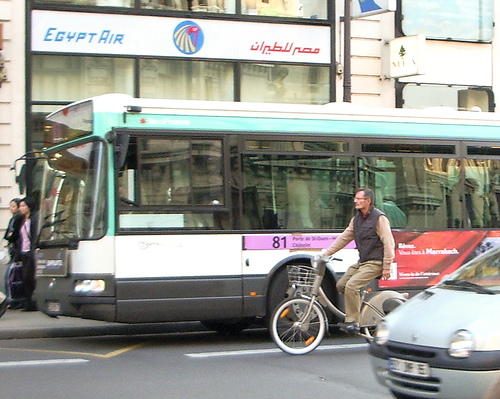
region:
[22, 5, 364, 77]
sign for Egypt Air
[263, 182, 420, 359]
man riding bike next to bus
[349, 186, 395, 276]
man wearing brown vest jacket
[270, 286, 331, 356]
two orange reflectors on bike tire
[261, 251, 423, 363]
Brown bike with basket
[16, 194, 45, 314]
woman in pink shirt on sidewalk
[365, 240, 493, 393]
small white car in street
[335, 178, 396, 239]
man wearing glasses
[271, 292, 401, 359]
white sidewall tires on bike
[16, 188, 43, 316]
woman with black hair and pants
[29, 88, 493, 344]
bus on city street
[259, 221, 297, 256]
number on side of bus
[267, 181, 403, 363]
man sitting on scooter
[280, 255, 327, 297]
basket on front of scooter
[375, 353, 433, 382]
license on front of car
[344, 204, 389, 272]
brown vest on man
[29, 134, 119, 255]
windshield on front of bus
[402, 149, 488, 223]
reflection on bus window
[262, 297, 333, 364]
scooter wheel with white wall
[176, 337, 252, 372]
white line in road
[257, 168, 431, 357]
an old man riding a bicycle down the road next to a large bus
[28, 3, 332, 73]
a sign on the building for Egypt Air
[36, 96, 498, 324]
a large city bus on the side of the road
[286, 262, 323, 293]
a silver basket on the front of the bicycle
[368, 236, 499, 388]
the front of a white car on the road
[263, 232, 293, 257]
number 81 on a purple sign on the side of the bus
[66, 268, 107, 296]
the front left headlight on the bus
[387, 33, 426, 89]
a white sign with a black logo on it on the building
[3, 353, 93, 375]
a white line painted in the street for cars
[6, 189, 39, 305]
two Asian women walking on the sidewalk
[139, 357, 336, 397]
this is the road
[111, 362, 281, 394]
the road is clear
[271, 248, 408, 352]
this is a bicycle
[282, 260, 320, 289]
this is a basket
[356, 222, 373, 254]
the jacket is brown in color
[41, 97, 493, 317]
this is a bus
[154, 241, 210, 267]
the bus is white in color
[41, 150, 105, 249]
this is a windscreen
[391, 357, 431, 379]
this is a number plate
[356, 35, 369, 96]
the wall is white in color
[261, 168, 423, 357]
man riding a bike down the street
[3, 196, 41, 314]
two people walking along the sidewalk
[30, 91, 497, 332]
large bus driving down the street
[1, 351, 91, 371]
white line painted on the ground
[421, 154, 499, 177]
reflection on the windpw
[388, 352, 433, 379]
long white license plate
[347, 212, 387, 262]
dark brown vest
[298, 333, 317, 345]
orange reflector in the spokes of the wheel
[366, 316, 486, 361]
two round headlights on the front of the car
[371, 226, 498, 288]
advertisement on the side of the bus